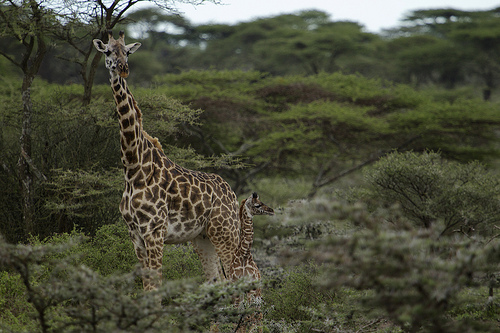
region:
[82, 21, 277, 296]
two giraffes in the forest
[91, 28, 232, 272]
mother giraffe in the forest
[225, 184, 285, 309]
baby giraffe in the forest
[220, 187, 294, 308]
baby giraffe near its mother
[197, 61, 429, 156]
green acacia trees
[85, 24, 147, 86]
giraffe head staring ahead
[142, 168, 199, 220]
brown and yellow giraffe pattern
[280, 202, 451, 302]
green trees surrounding a giraffe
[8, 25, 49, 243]
tree trunk with growing moss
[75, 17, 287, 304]
giraffes roaming in the forest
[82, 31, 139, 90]
giraffe is very tall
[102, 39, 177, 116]
giraffe is very tall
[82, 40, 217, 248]
giraffe is very tall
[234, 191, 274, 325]
Baby giraffe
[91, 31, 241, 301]
A giraffe looking away.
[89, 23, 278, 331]
Adult with baby giraffe.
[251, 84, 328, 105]
Brown trees leaves.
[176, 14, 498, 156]
A treeline in the distance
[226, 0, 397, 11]
Cloudless blue sky above canopy.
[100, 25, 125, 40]
Ears of a giraffe.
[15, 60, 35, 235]
Skinny tree trunk.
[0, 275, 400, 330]
Plant brush on the ground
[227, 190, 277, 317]
Baby giraffe looking at something.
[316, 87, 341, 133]
There is a dark green color to the trees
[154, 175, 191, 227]
The zebra has brown and yellow spots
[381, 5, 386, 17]
The sky has a rather bright white color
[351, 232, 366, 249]
There is an off-green color to the bushes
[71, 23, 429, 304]
This photo was taken in the continent of Africa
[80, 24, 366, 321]
This photo was taken in the country of South Africa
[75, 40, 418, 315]
Mickey Zanders is the one who took the photo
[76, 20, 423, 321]
Jackson Zewiski is the one who published the photo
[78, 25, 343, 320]
The temperature is 85 degrees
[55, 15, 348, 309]
The season when the photo was taken is summer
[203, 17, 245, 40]
top of green trees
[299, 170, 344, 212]
large black branch on the tree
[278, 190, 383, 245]
white moss on tree top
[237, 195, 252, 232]
small brown comb on the baby giraffe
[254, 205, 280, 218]
small stripes on the baby giraffe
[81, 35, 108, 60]
black spot in the ear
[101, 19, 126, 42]
black tipped giraffe's ear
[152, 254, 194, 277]
green bush on the forest floor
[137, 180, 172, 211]
brown and white stripe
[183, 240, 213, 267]
white under side of leg